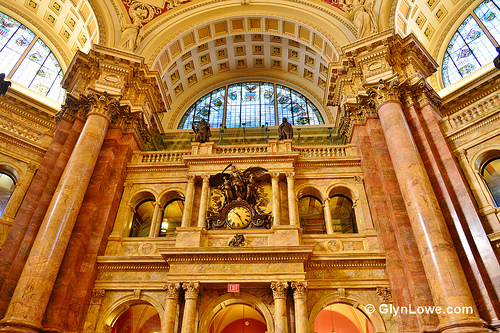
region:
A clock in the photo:
[220, 200, 258, 226]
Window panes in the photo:
[201, 88, 295, 122]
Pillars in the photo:
[272, 172, 299, 232]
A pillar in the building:
[330, 59, 484, 314]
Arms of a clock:
[234, 209, 249, 229]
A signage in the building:
[223, 279, 247, 297]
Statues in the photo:
[182, 117, 296, 142]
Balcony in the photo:
[120, 198, 358, 275]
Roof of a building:
[98, 0, 169, 25]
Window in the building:
[474, 160, 498, 200]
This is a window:
[234, 55, 345, 139]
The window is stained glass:
[173, 90, 298, 145]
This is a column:
[55, 131, 125, 252]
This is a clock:
[201, 151, 299, 301]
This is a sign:
[220, 245, 235, 306]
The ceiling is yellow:
[158, 70, 291, 115]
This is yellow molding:
[182, 30, 253, 111]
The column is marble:
[336, 160, 446, 276]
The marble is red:
[400, 147, 450, 263]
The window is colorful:
[459, 60, 491, 95]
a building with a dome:
[3, 0, 499, 332]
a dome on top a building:
[9, 3, 486, 94]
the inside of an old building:
[3, 7, 498, 327]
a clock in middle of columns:
[177, 170, 297, 231]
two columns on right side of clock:
[226, 163, 298, 228]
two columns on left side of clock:
[176, 169, 257, 231]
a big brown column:
[371, 93, 488, 330]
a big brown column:
[7, 97, 114, 327]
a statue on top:
[271, 108, 296, 144]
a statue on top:
[181, 109, 219, 149]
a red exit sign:
[222, 279, 243, 295]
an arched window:
[174, 71, 335, 139]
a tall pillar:
[0, 90, 120, 330]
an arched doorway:
[200, 291, 270, 329]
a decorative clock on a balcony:
[206, 163, 273, 230]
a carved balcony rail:
[118, 228, 368, 255]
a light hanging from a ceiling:
[159, 202, 171, 234]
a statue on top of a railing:
[275, 115, 292, 141]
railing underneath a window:
[129, 138, 362, 170]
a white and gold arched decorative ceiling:
[148, 10, 347, 116]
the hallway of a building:
[32, 14, 484, 327]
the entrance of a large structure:
[14, 12, 463, 310]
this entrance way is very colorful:
[67, 111, 407, 332]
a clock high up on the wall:
[200, 189, 278, 233]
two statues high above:
[177, 106, 300, 146]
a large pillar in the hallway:
[37, 59, 132, 322]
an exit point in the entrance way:
[155, 246, 314, 332]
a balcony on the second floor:
[142, 167, 357, 258]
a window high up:
[189, 77, 339, 147]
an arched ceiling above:
[114, 19, 373, 96]